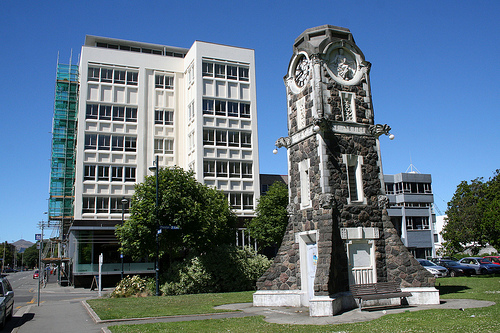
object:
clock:
[322, 40, 367, 86]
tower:
[248, 23, 441, 316]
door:
[295, 231, 318, 307]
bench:
[350, 282, 413, 311]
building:
[44, 32, 441, 287]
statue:
[370, 123, 396, 140]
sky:
[0, 0, 500, 243]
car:
[33, 269, 47, 280]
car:
[0, 274, 17, 333]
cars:
[415, 259, 448, 278]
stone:
[278, 273, 290, 283]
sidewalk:
[10, 279, 500, 332]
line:
[425, 247, 427, 256]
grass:
[87, 270, 500, 333]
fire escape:
[46, 62, 80, 229]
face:
[287, 51, 312, 95]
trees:
[440, 169, 500, 260]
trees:
[114, 163, 234, 271]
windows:
[81, 193, 96, 215]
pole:
[153, 159, 160, 296]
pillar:
[313, 200, 344, 296]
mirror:
[6, 290, 15, 299]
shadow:
[433, 285, 471, 295]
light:
[272, 148, 279, 155]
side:
[257, 29, 329, 295]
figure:
[338, 48, 347, 55]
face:
[323, 41, 365, 85]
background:
[0, 2, 500, 288]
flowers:
[132, 281, 138, 285]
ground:
[0, 270, 500, 333]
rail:
[345, 266, 377, 285]